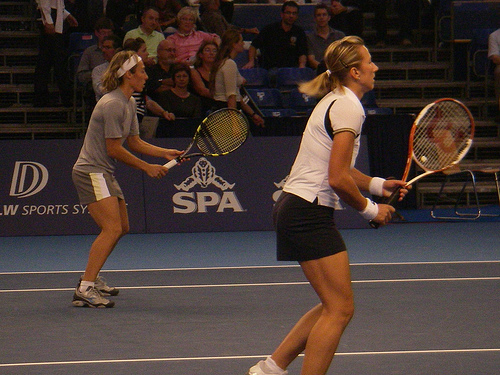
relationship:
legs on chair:
[426, 168, 498, 219] [422, 154, 499, 221]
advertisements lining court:
[168, 159, 250, 224] [11, 223, 488, 373]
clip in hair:
[338, 58, 351, 68] [103, 63, 116, 77]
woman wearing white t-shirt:
[245, 18, 417, 372] [281, 82, 368, 211]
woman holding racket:
[70, 46, 191, 310] [155, 104, 248, 174]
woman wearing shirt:
[245, 18, 417, 372] [157, 27, 217, 67]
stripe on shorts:
[85, 170, 111, 201] [70, 168, 125, 206]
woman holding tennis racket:
[70, 46, 191, 310] [159, 103, 254, 170]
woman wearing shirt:
[167, 9, 217, 61] [160, 28, 221, 63]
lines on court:
[8, 265, 497, 353] [2, 207, 499, 371]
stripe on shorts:
[89, 170, 112, 201] [63, 162, 152, 212]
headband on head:
[113, 56, 134, 76] [112, 52, 152, 105]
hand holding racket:
[138, 142, 152, 151] [160, 107, 247, 171]